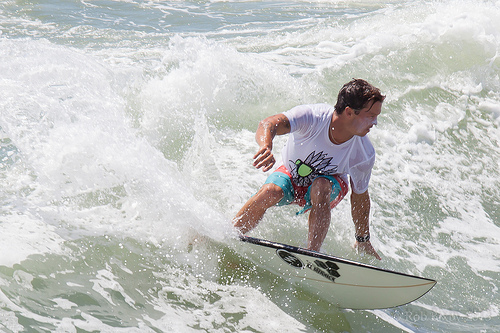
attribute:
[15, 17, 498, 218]
wave — large, of ocean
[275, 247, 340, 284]
design — on bottom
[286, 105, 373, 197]
shirt — white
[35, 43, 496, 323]
water — ocean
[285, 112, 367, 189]
shirt — white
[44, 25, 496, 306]
water — clear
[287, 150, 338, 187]
design — green, grey, black, white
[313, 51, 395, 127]
hair — wet, brown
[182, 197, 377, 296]
line — straight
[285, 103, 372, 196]
t-shirt — white, short sleeve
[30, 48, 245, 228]
froth — white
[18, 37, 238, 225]
splash — water, white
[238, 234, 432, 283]
details — black